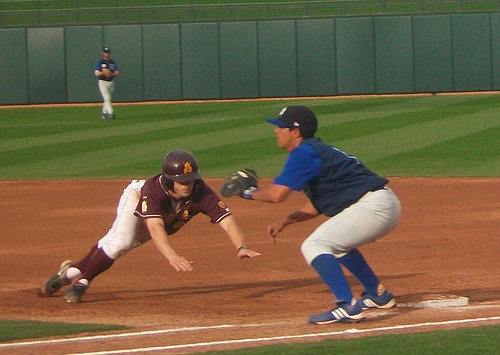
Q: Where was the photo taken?
A: It was taken at the field.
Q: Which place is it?
A: It is a field.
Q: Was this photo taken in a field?
A: Yes, it was taken in a field.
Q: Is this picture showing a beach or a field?
A: It is showing a field.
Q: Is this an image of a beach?
A: No, the picture is showing a field.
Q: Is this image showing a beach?
A: No, the picture is showing a field.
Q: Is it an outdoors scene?
A: Yes, it is outdoors.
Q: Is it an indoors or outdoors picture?
A: It is outdoors.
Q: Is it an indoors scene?
A: No, it is outdoors.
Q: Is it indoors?
A: No, it is outdoors.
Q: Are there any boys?
A: No, there are no boys.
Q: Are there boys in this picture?
A: No, there are no boys.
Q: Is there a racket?
A: No, there are no rackets.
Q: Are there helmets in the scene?
A: Yes, there is a helmet.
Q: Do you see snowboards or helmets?
A: Yes, there is a helmet.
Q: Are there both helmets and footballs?
A: No, there is a helmet but no footballs.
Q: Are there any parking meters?
A: No, there are no parking meters.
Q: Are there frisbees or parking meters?
A: No, there are no parking meters or frisbees.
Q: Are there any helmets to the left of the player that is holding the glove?
A: Yes, there is a helmet to the left of the player.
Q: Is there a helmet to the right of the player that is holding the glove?
A: No, the helmet is to the left of the player.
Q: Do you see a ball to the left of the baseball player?
A: No, there is a helmet to the left of the player.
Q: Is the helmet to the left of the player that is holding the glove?
A: Yes, the helmet is to the left of the player.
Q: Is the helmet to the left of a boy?
A: No, the helmet is to the left of the player.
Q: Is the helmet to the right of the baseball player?
A: No, the helmet is to the left of the player.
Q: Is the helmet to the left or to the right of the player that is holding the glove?
A: The helmet is to the left of the player.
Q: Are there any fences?
A: Yes, there is a fence.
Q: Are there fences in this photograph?
A: Yes, there is a fence.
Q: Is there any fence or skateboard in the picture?
A: Yes, there is a fence.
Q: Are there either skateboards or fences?
A: Yes, there is a fence.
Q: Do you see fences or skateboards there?
A: Yes, there is a fence.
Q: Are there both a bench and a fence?
A: No, there is a fence but no benches.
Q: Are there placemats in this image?
A: No, there are no placemats.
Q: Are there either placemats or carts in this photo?
A: No, there are no placemats or carts.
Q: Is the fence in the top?
A: Yes, the fence is in the top of the image.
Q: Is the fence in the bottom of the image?
A: No, the fence is in the top of the image.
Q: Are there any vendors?
A: No, there are no vendors.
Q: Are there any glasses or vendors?
A: No, there are no vendors or glasses.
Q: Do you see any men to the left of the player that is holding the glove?
A: Yes, there is a man to the left of the player.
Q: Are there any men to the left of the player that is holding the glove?
A: Yes, there is a man to the left of the player.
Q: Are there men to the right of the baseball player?
A: No, the man is to the left of the player.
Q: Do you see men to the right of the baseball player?
A: No, the man is to the left of the player.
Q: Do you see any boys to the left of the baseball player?
A: No, there is a man to the left of the player.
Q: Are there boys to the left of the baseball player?
A: No, there is a man to the left of the player.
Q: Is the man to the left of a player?
A: Yes, the man is to the left of a player.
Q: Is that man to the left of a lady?
A: No, the man is to the left of a player.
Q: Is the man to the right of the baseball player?
A: No, the man is to the left of the player.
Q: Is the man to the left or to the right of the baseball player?
A: The man is to the left of the player.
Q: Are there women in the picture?
A: No, there are no women.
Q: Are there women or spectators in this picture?
A: No, there are no women or spectators.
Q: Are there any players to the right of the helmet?
A: Yes, there is a player to the right of the helmet.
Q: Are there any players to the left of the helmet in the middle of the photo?
A: No, the player is to the right of the helmet.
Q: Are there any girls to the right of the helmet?
A: No, there is a player to the right of the helmet.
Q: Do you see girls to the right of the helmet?
A: No, there is a player to the right of the helmet.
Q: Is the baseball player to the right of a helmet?
A: Yes, the player is to the right of a helmet.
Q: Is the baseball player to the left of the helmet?
A: No, the player is to the right of the helmet.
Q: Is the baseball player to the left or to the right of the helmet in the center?
A: The player is to the right of the helmet.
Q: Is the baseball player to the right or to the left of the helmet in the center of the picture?
A: The player is to the right of the helmet.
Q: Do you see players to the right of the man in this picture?
A: Yes, there is a player to the right of the man.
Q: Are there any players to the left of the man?
A: No, the player is to the right of the man.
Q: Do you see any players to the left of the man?
A: No, the player is to the right of the man.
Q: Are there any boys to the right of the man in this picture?
A: No, there is a player to the right of the man.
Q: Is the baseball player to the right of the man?
A: Yes, the player is to the right of the man.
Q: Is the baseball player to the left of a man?
A: No, the player is to the right of a man.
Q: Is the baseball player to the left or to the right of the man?
A: The player is to the right of the man.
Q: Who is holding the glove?
A: The player is holding the glove.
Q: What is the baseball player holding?
A: The player is holding the glove.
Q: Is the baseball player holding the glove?
A: Yes, the player is holding the glove.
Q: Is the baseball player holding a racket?
A: No, the player is holding the glove.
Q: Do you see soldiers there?
A: No, there are no soldiers.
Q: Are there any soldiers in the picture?
A: No, there are no soldiers.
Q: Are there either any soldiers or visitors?
A: No, there are no soldiers or visitors.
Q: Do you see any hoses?
A: No, there are no hoses.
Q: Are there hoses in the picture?
A: No, there are no hoses.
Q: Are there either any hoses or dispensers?
A: No, there are no hoses or dispensers.